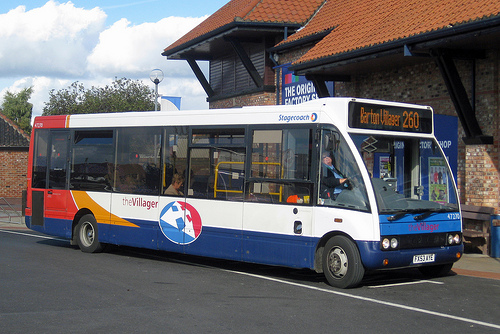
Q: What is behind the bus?
A: A building.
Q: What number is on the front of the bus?
A: 260.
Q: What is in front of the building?
A: A bus.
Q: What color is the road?
A: Black.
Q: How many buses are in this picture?
A: One.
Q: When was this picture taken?
A: Day time.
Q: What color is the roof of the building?
A: Brown.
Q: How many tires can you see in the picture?
A: Two.